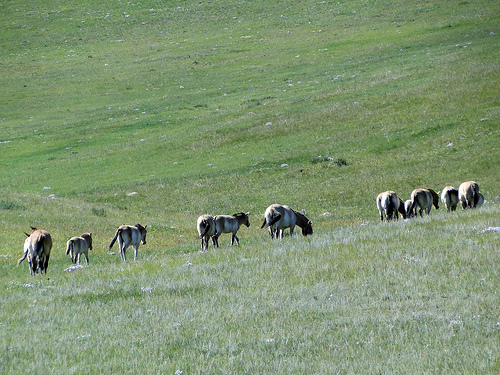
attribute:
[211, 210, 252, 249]
horse — large, brown, white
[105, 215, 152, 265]
horse — brown, white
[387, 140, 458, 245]
horse — white, large, brown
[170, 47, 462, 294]
field — open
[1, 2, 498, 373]
field — open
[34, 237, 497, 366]
grass — short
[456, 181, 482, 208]
horse — white, large, brown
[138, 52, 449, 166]
field — large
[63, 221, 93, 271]
horse — large, brown, white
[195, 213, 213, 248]
horse — large, brown, white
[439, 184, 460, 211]
horse — large, brown, white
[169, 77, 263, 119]
rocks — gray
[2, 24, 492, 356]
field — grass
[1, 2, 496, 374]
grass — green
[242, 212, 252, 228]
head — Brown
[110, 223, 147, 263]
animal — white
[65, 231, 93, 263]
animal — white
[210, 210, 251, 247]
animal — white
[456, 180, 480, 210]
animal — white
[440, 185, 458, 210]
animal — white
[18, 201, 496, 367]
field — open